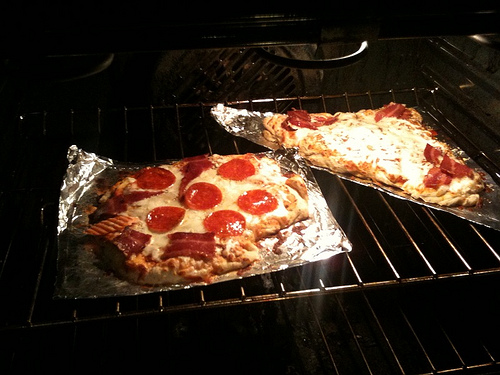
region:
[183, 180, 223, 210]
A slice of crispy pepperoni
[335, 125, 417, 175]
Melted mozzarella cheese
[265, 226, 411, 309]
tin foil on an oven rack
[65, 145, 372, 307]
Pizza on tin foil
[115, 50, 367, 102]
Oven fan in the back of the oven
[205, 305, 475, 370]
The lower oven rack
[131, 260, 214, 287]
Pizza crust with cheese on it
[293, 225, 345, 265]
Light reflecting on tin foil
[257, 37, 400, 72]
A wire inside an oven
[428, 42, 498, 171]
The right wall of an oven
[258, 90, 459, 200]
A triangular shaped pizza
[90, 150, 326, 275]
A round pizza resting on tin foil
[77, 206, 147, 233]
A spiral pasta noodle stuck on top of pizza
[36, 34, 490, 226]
An oven baking pizzas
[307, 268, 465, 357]
Two oven racks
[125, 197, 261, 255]
Pepperoni and bacon nestled in melted cheese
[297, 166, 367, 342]
Light reflecting in the oven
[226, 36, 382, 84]
The heating coils on top of the oven inside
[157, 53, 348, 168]
A circular air vent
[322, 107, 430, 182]
No meat in the middle of this pizza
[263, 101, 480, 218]
The triangular piece of pizza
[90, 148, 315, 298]
The circular piece of pizza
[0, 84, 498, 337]
The rack the pizza is on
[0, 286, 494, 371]
The rack below the one the pizza is on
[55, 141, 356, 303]
The aluminum the circular pizza is on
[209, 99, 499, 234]
The aluminum the triangular pizza is on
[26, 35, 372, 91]
The coils at the top of the freezer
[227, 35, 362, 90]
Where the light us coming from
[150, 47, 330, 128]
The circular vent in the back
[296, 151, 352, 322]
The glare off of the tin foil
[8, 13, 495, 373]
an oven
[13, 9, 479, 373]
pizza is in the oven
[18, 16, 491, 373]
the pizza is on the top rack of the oven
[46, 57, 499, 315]
two slices of pizza in the oven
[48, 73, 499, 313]
the pizza is on aluminum foil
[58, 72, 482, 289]
the pizza has pepperoni on it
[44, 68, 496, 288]
the pizza has cheese and toppings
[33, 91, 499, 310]
a metal rack with pizza on it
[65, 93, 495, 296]
the pizza has lumpy crust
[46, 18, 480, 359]
the oven light is on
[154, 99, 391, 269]
two pizza slices in an oven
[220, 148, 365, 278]
light reflects off of a sheet of metal foil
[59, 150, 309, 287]
a pizza slice with pepperoni and bacon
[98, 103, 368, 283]
two pizza slices on folded pieces of foil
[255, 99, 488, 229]
a triangular slice of pizza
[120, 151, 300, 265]
five pieces of pepperoni on a slice of pizza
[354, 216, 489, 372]
two racks in a dark oven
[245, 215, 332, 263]
cheesed melted from a pizza slice onto a piece of foil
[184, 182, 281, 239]
grease shines on top of pieces of pepperoni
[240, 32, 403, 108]
the heating element of an oven